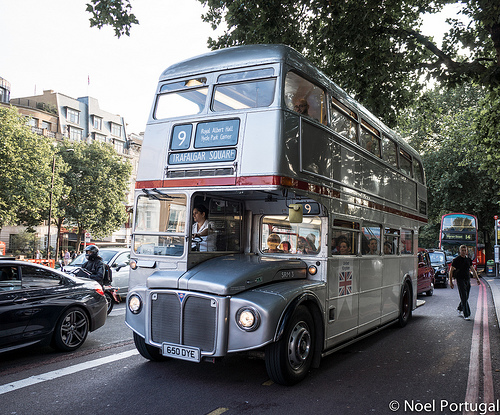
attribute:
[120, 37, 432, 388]
bus — double decker, grey, silver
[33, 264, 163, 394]
car — black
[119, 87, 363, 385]
bus — silver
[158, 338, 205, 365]
plate — white, number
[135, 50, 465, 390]
bus — illuminated 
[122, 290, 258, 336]
lights — on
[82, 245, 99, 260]
helmet — black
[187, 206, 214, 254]
driver — woman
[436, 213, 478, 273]
bus — DOUBLE DECKER, red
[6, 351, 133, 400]
line — white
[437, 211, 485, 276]
bus — double decker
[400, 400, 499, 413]
name — Noel Portugal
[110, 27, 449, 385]
bus — double decker, old, grey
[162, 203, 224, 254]
driver — woman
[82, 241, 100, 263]
helmet — black 